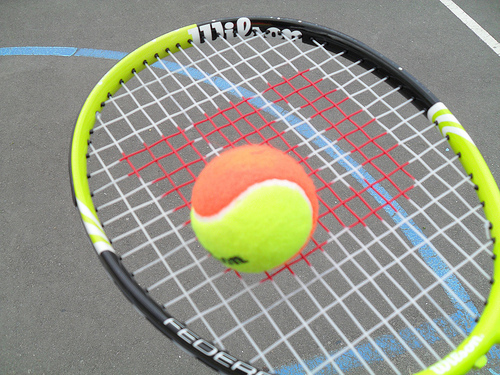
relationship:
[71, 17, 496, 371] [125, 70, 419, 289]
racquet has "w"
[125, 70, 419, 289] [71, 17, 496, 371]
logo on top of racquet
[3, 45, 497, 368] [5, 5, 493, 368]
lines on top of court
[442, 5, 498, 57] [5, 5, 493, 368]
line on top of court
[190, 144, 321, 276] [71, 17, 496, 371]
ball on top of racquet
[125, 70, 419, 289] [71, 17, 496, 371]
logo on side of racquet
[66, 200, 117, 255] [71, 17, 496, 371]
design on side of racquet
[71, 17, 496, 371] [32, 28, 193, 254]
racquet has edge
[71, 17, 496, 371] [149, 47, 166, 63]
racquet has hole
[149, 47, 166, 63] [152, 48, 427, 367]
hole for string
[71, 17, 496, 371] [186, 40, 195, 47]
racquet has hole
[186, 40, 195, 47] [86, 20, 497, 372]
hole for string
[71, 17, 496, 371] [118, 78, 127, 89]
racquet has hole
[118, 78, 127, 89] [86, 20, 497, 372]
hole for string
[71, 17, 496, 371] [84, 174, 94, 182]
racquet has hole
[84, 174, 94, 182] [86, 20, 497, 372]
hole for string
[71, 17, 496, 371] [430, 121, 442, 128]
racquet has hole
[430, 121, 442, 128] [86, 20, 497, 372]
hole for string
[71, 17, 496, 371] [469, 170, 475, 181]
racquet has hole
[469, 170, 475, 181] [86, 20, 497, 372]
hole for string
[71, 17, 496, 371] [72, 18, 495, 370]
racquet has rim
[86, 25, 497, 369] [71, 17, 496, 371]
strings are across racquet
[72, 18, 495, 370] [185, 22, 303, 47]
rim has letters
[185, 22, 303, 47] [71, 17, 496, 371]
letters on top of racquet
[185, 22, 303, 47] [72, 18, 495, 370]
letters on top of rim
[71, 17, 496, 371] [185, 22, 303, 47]
racquet has letters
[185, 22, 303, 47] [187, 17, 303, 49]
letters spell wilson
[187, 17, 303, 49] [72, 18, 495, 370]
wilson on top of rim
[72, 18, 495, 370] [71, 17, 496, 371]
rim around racquet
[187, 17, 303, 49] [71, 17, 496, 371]
wilson on top of racquet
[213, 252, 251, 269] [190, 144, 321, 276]
writing on top of ball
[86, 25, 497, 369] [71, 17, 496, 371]
strings are crossing racquet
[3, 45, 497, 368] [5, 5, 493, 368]
lines are on top of court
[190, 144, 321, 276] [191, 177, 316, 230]
ball has seam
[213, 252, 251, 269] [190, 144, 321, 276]
writing printed on top of ball